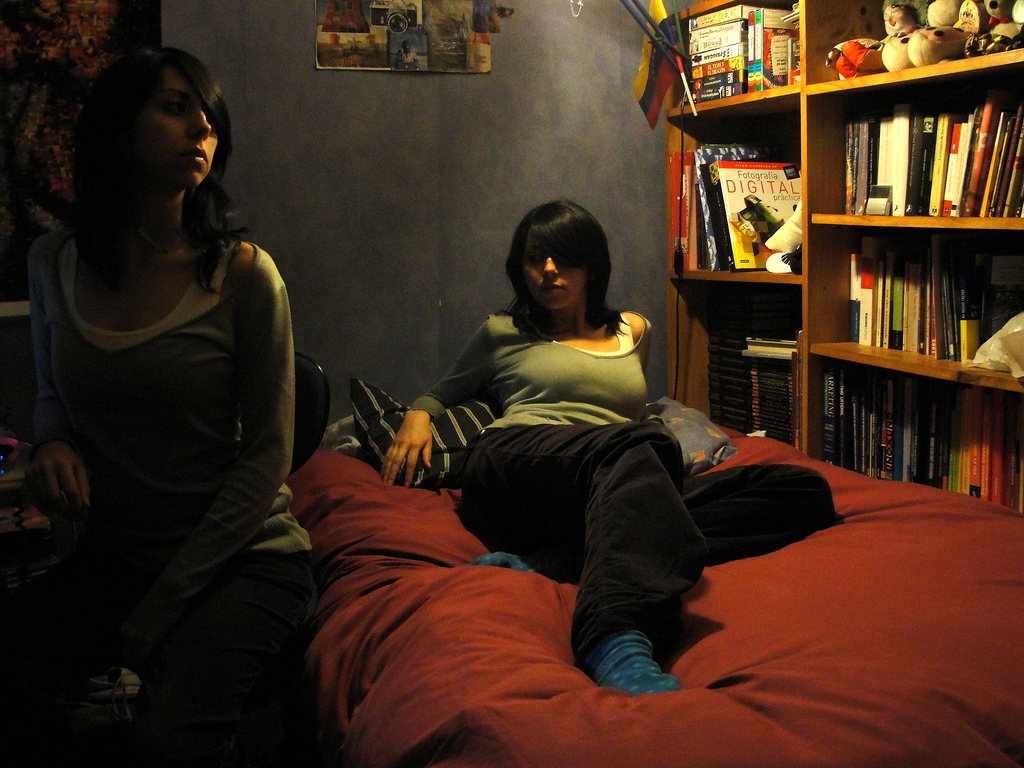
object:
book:
[706, 161, 802, 273]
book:
[707, 279, 806, 449]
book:
[685, 143, 800, 272]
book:
[668, 152, 696, 271]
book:
[844, 117, 857, 216]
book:
[846, 116, 870, 215]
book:
[925, 112, 982, 216]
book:
[860, 237, 876, 346]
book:
[821, 357, 837, 466]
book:
[859, 104, 927, 215]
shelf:
[666, 274, 809, 457]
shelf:
[670, 269, 812, 284]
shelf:
[805, 213, 1021, 230]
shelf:
[802, 341, 1021, 389]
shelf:
[810, 349, 1023, 516]